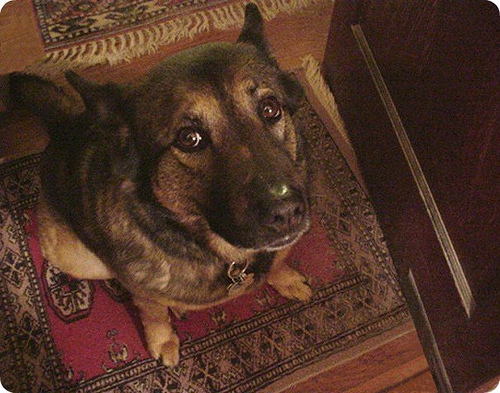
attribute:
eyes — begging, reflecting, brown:
[154, 94, 293, 150]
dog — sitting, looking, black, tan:
[4, 2, 359, 372]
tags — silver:
[218, 255, 263, 300]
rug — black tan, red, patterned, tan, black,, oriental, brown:
[2, 66, 440, 393]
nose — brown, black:
[256, 185, 307, 233]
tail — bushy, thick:
[5, 63, 91, 140]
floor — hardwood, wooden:
[5, 1, 443, 392]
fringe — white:
[32, 2, 314, 62]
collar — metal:
[161, 217, 250, 269]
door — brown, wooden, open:
[324, 1, 496, 385]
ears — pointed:
[58, 2, 314, 90]